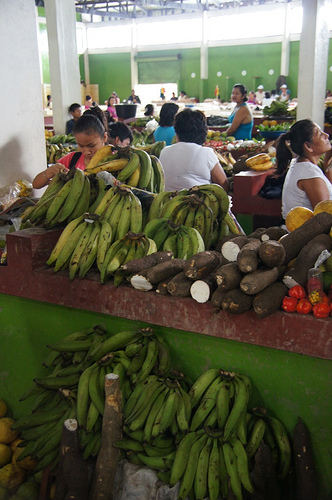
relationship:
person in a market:
[231, 85, 253, 138] [2, 4, 328, 500]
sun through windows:
[42, 1, 320, 49] [44, 8, 332, 54]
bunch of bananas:
[33, 171, 101, 222] [28, 171, 100, 227]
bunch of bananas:
[93, 146, 163, 193] [92, 137, 163, 188]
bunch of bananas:
[142, 216, 205, 257] [157, 181, 228, 248]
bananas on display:
[28, 171, 100, 227] [7, 149, 239, 283]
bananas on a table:
[157, 181, 228, 248] [3, 202, 332, 358]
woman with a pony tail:
[33, 106, 125, 204] [79, 104, 110, 127]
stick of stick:
[92, 370, 126, 496] [88, 365, 129, 498]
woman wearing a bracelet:
[33, 106, 125, 204] [43, 169, 50, 183]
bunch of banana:
[157, 181, 228, 248] [145, 185, 225, 245]